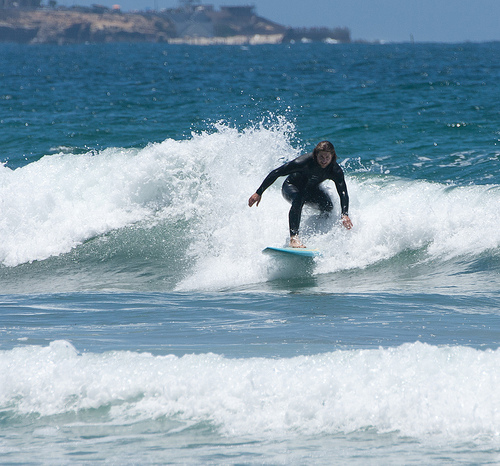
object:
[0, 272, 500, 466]
water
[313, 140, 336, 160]
blonde hair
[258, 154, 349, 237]
suit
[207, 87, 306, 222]
ocean spray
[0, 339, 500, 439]
wave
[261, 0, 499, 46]
cloudless sky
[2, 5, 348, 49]
island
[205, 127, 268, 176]
wave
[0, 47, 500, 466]
ocean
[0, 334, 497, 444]
foam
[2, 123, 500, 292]
tide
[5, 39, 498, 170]
blue water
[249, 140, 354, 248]
man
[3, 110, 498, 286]
white wave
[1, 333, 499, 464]
tide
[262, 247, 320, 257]
surf board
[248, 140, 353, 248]
woman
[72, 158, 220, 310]
waters